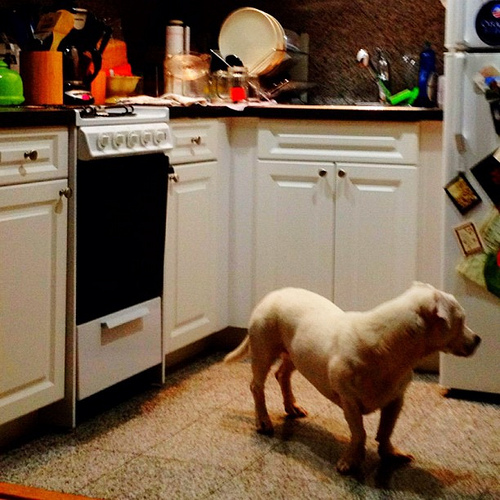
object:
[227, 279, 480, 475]
dog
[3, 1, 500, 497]
kitchen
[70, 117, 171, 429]
oven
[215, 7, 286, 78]
dishes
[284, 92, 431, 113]
sink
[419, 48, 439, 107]
soap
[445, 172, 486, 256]
magnets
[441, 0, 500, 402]
refrigerator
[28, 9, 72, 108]
utensils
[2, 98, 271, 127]
counter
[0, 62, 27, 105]
teapot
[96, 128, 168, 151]
buttons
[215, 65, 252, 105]
mug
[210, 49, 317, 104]
strainer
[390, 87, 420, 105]
sponge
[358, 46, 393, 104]
fixture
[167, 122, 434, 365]
cabinets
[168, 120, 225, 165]
drawer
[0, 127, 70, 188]
drawer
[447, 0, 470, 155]
handle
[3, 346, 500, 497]
floor